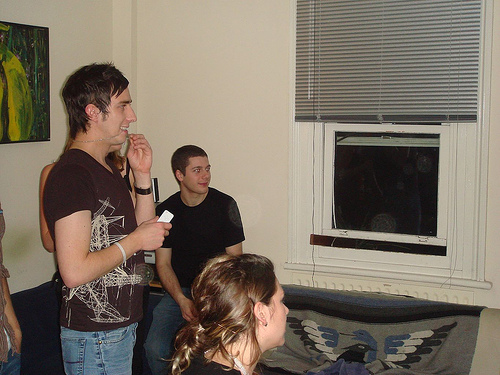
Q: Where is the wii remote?
A: Guy's hand.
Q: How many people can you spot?
A: Five.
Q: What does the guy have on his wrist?
A: Watch.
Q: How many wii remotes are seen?
A: One.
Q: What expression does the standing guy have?
A: Smile.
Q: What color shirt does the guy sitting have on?
A: Black.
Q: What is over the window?
A: Blinds.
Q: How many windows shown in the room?
A: One.